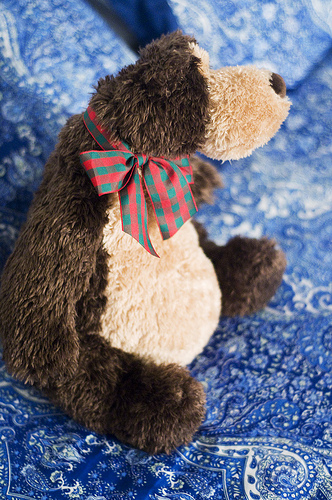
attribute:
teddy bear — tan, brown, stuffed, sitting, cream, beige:
[5, 40, 291, 452]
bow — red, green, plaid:
[80, 111, 203, 247]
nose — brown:
[268, 72, 290, 108]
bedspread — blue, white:
[12, 19, 326, 487]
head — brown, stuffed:
[112, 35, 290, 167]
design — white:
[217, 355, 327, 499]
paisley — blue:
[204, 345, 323, 497]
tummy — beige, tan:
[113, 253, 221, 359]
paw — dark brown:
[161, 377, 199, 441]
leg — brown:
[142, 246, 282, 460]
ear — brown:
[134, 47, 189, 94]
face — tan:
[185, 41, 294, 167]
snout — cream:
[233, 65, 290, 147]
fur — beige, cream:
[122, 56, 277, 365]